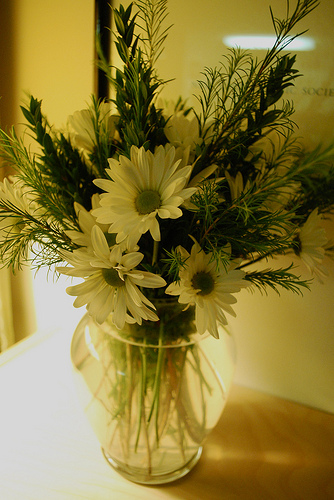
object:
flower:
[163, 238, 253, 341]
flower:
[88, 142, 199, 252]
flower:
[54, 224, 168, 330]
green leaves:
[262, 279, 280, 298]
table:
[0, 322, 334, 500]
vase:
[68, 286, 237, 485]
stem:
[147, 314, 165, 423]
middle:
[133, 188, 163, 215]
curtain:
[0, 208, 38, 352]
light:
[0, 233, 176, 500]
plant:
[0, 0, 334, 479]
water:
[68, 306, 238, 477]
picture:
[91, 1, 334, 258]